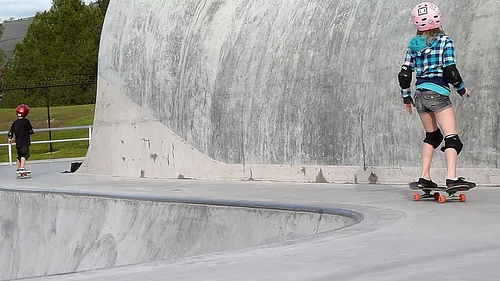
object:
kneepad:
[441, 135, 463, 156]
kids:
[394, 1, 484, 193]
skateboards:
[412, 188, 472, 204]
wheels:
[433, 195, 443, 202]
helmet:
[408, 2, 444, 34]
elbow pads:
[396, 70, 414, 82]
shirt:
[396, 33, 464, 97]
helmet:
[14, 103, 31, 117]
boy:
[6, 104, 36, 173]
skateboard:
[15, 168, 35, 177]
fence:
[0, 83, 100, 157]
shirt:
[10, 118, 38, 145]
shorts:
[11, 140, 32, 161]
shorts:
[414, 90, 450, 114]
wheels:
[21, 174, 26, 179]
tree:
[17, 0, 94, 107]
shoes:
[445, 176, 475, 188]